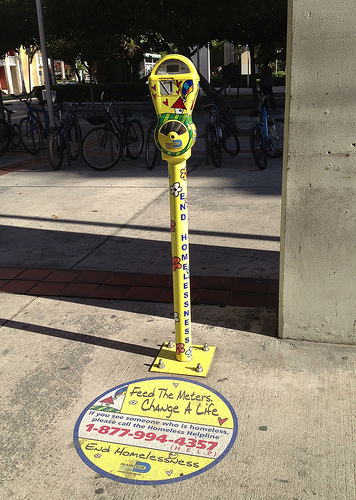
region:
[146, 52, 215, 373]
A yellow parking meter on the street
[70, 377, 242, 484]
A yellow and blue sign on the sidewalk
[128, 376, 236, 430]
The top half of sign says "Feed the meters change a life"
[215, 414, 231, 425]
A red heart on the top of the sign to the right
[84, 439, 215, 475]
Bottom half of the sign says, "End Homelessness"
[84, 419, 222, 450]
Center of the signs has phone number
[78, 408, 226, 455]
The center of the sign is white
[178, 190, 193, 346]
Writing on the side of the meter pole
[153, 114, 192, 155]
Green on the center of the meter at the top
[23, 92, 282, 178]
Bikecycles in behind the parking meter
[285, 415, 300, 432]
part of a wall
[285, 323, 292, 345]
edge of a wall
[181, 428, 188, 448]
part of a sticker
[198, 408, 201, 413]
edge of a sticker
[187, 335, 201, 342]
edge of a post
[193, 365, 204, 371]
part of a bolt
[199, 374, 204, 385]
edge of a post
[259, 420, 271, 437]
side of a road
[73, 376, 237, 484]
circle painted on the ground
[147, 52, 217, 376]
bright yellow parking meter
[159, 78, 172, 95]
slot for money for parking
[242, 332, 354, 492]
sidewalk near a curb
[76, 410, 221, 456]
1-877 number to call for homeless people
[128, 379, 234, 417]
this sign says: feed the meters. change a life.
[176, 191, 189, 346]
parking meter says: end homelessness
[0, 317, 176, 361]
parking meter shadow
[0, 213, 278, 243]
shadow of thin pole in background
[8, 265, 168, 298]
bricks under the threshold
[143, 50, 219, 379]
a yellow meter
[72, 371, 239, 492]
a sign on the ground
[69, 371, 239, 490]
a multi-colored sign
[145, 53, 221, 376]
a multi-colored meter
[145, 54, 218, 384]
a meter on the pavement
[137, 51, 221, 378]
a meter with blue lettering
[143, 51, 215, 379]
a meter in the city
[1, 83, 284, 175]
a row of bicycles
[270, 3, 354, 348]
a cement post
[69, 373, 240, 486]
a sign with a phone number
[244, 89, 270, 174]
bike on a side walk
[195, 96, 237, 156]
bike on a side walk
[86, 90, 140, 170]
bike on a sidewalk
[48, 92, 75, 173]
bike on a side walk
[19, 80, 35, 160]
bike on a sidewalk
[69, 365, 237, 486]
sign on a sidewalk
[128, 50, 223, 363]
parking meter on sidewalk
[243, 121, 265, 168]
tire on a bike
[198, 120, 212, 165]
tire on a bike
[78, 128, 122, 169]
tire on a bike